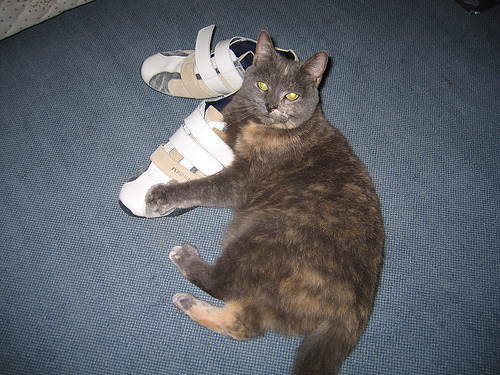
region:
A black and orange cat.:
[145, 31, 388, 373]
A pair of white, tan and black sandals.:
[115, 21, 301, 218]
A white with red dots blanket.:
[0, 0, 96, 44]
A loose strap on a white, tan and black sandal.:
[139, 22, 295, 104]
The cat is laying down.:
[142, 30, 384, 373]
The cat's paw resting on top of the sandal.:
[114, 30, 340, 222]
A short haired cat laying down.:
[143, 26, 387, 371]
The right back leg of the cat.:
[170, 241, 235, 291]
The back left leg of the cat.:
[172, 290, 252, 340]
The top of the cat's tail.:
[292, 331, 339, 371]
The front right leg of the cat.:
[150, 177, 236, 202]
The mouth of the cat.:
[257, 107, 273, 117]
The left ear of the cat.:
[255, 31, 270, 56]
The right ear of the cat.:
[304, 46, 329, 78]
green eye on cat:
[279, 79, 308, 106]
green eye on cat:
[250, 74, 272, 94]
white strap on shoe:
[189, 104, 239, 166]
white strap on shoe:
[168, 128, 230, 181]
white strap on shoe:
[216, 40, 251, 101]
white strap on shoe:
[185, 3, 235, 102]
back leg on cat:
[170, 236, 249, 276]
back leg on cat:
[168, 294, 274, 361]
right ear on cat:
[249, 26, 276, 67]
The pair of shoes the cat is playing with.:
[99, 30, 254, 222]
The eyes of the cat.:
[253, 76, 312, 108]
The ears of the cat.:
[253, 51, 326, 73]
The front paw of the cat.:
[138, 177, 195, 222]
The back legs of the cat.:
[162, 241, 259, 343]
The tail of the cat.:
[299, 325, 364, 372]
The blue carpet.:
[14, 8, 496, 363]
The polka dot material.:
[3, 2, 98, 42]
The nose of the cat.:
[266, 97, 283, 116]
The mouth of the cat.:
[251, 106, 299, 130]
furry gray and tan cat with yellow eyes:
[146, 25, 388, 374]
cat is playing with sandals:
[119, 25, 381, 370]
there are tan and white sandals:
[111, 22, 301, 223]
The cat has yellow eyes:
[250, 70, 307, 106]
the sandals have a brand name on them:
[166, 160, 193, 180]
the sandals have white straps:
[114, 24, 302, 219]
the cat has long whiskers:
[225, 52, 330, 132]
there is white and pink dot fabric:
[1, 1, 100, 39]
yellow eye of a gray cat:
[282, 90, 299, 103]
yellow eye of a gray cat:
[252, 78, 272, 95]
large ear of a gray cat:
[300, 48, 331, 78]